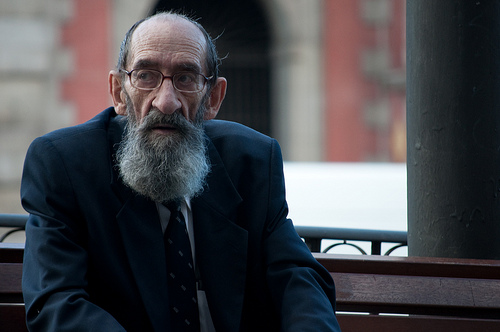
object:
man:
[20, 9, 341, 331]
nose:
[150, 79, 182, 114]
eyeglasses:
[118, 68, 215, 93]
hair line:
[140, 8, 194, 20]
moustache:
[111, 107, 213, 203]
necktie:
[162, 197, 200, 331]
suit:
[20, 105, 343, 331]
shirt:
[155, 191, 217, 331]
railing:
[0, 214, 408, 257]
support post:
[405, 0, 500, 260]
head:
[108, 8, 228, 152]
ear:
[107, 70, 128, 116]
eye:
[137, 71, 157, 82]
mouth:
[146, 122, 182, 135]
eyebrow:
[133, 58, 161, 69]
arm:
[19, 137, 124, 331]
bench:
[0, 245, 499, 331]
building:
[0, 0, 407, 243]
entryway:
[143, 0, 274, 163]